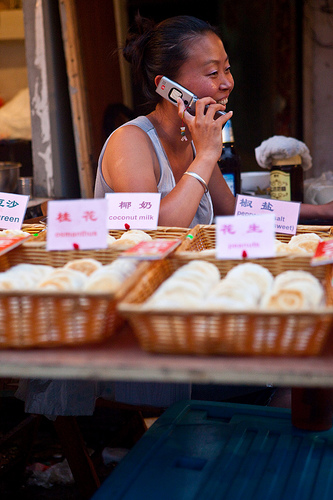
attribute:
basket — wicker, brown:
[25, 218, 186, 267]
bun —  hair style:
[99, 23, 182, 80]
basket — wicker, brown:
[112, 253, 331, 359]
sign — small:
[234, 194, 299, 235]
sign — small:
[99, 188, 164, 234]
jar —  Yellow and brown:
[263, 155, 310, 203]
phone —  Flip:
[151, 73, 233, 132]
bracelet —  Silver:
[177, 167, 212, 196]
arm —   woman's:
[156, 96, 237, 232]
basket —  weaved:
[132, 302, 278, 352]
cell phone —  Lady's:
[157, 78, 226, 123]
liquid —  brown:
[259, 140, 314, 211]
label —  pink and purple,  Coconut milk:
[105, 193, 161, 229]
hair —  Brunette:
[109, 5, 223, 118]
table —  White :
[3, 347, 331, 388]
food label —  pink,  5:
[213, 213, 276, 258]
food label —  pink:
[45, 198, 110, 252]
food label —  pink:
[101, 190, 164, 229]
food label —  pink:
[1, 189, 31, 232]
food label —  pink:
[236, 188, 302, 233]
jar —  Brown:
[265, 149, 305, 203]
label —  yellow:
[267, 168, 292, 201]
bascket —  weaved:
[175, 224, 331, 281]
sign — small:
[0, 190, 29, 231]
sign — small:
[45, 199, 109, 250]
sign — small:
[103, 190, 159, 229]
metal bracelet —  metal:
[182, 168, 211, 194]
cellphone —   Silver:
[157, 75, 233, 130]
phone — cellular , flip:
[151, 76, 229, 129]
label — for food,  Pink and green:
[0, 191, 30, 232]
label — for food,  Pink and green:
[45, 197, 109, 251]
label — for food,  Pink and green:
[103, 191, 160, 230]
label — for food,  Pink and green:
[233, 192, 301, 235]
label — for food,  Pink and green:
[214, 212, 277, 260]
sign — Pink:
[231, 187, 300, 235]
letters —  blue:
[236, 196, 272, 209]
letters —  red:
[217, 220, 263, 233]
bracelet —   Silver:
[185, 166, 206, 189]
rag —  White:
[253, 135, 313, 170]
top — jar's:
[273, 156, 301, 164]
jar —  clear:
[270, 156, 302, 202]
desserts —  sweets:
[0, 219, 332, 358]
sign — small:
[210, 213, 279, 257]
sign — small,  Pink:
[44, 195, 108, 250]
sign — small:
[212, 213, 274, 260]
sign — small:
[231, 195, 304, 238]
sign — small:
[46, 195, 113, 249]